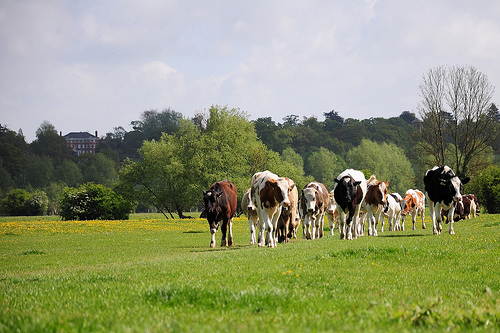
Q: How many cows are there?
A: 12.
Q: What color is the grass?
A: Green.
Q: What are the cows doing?
A: Walking.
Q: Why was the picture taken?
A: To capture the cows.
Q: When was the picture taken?
A: In the daytime.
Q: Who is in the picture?
A: Cows.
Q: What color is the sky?
A: Blue.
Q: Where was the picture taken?
A: In a field.